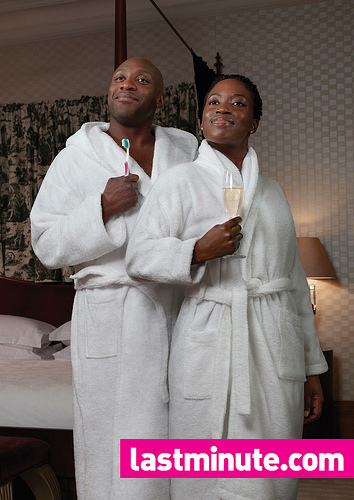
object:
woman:
[124, 74, 328, 499]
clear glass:
[222, 170, 245, 219]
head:
[108, 56, 164, 127]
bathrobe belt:
[183, 277, 292, 442]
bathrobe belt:
[70, 264, 170, 403]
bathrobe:
[29, 120, 197, 498]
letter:
[182, 451, 212, 473]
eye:
[111, 74, 126, 82]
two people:
[29, 54, 330, 499]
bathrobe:
[124, 140, 328, 500]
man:
[29, 56, 199, 500]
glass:
[220, 165, 246, 262]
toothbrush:
[121, 137, 130, 175]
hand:
[100, 174, 140, 225]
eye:
[232, 100, 244, 107]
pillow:
[0, 310, 57, 349]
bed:
[0, 273, 77, 430]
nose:
[213, 102, 235, 116]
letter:
[156, 450, 175, 472]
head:
[201, 71, 261, 149]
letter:
[208, 443, 218, 473]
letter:
[218, 450, 234, 471]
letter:
[234, 451, 251, 471]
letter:
[251, 446, 263, 472]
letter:
[263, 450, 280, 473]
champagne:
[223, 185, 243, 211]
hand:
[190, 213, 243, 266]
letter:
[129, 445, 142, 471]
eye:
[206, 99, 217, 109]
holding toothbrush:
[99, 137, 140, 213]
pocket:
[83, 294, 121, 358]